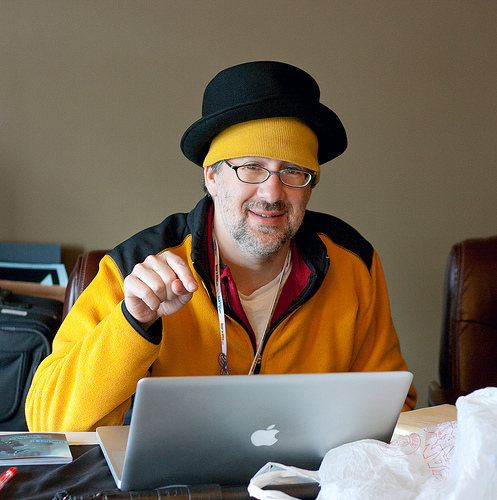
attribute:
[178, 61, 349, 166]
hat — felt, black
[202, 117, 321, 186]
hat — knit, yellow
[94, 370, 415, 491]
laptop — apple macbook pro, apple, silver, open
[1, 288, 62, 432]
bag — black, tall, suitcase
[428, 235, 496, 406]
chair — for office, dark brown, leather, brown, for desk, empty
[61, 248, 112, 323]
chair — for office, dark brown, leather, brown, for desk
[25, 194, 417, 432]
sweater — fleece, zip up, yellow, black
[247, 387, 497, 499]
grocery bag — plastic, white, empty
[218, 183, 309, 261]
beard — grey, goatee, salt, pepper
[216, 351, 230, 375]
pin — blue ribbon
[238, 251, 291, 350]
under shirt — white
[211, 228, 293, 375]
lanyard — for keys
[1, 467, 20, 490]
pen — red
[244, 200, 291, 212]
moustache — salt, pepper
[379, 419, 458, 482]
writing — red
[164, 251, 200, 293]
finger — pointing